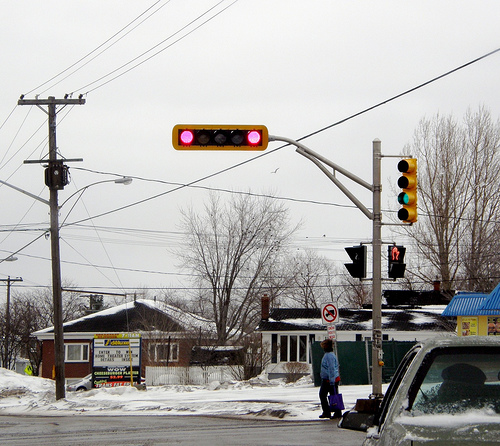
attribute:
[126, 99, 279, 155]
lights — red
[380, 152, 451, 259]
lights — green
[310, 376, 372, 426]
pants — black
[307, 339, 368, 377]
jacket — blue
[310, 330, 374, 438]
woman — carrying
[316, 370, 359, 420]
bag — blue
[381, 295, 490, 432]
car — covered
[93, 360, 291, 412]
snow — white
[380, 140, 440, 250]
light — green, shining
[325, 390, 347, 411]
bag — blue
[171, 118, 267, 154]
light — wide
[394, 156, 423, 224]
light — tall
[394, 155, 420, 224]
light — yellow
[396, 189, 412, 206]
light — green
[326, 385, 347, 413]
bag — blue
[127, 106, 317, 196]
lights — red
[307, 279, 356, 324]
sign — red, white, black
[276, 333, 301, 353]
lines — white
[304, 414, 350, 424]
foot — lifted